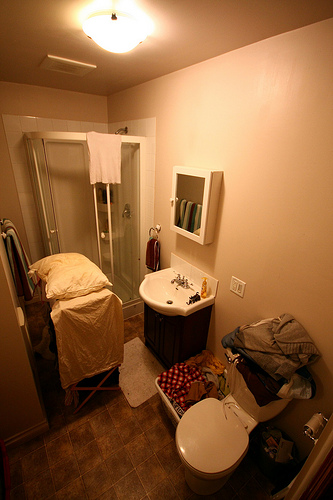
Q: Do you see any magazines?
A: No, there are no magazines.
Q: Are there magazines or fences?
A: No, there are no magazines or fences.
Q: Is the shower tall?
A: Yes, the shower is tall.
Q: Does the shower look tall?
A: Yes, the shower is tall.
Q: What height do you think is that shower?
A: The shower is tall.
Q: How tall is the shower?
A: The shower is tall.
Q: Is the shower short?
A: No, the shower is tall.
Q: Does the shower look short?
A: No, the shower is tall.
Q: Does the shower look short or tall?
A: The shower is tall.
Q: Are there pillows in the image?
A: Yes, there is a pillow.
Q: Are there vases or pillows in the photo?
A: Yes, there is a pillow.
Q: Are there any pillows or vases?
A: Yes, there is a pillow.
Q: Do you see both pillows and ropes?
A: No, there is a pillow but no ropes.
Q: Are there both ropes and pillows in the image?
A: No, there is a pillow but no ropes.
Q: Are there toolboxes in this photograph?
A: No, there are no toolboxes.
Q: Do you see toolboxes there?
A: No, there are no toolboxes.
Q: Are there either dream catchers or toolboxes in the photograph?
A: No, there are no toolboxes or dream catchers.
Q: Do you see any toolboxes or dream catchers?
A: No, there are no toolboxes or dream catchers.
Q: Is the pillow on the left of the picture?
A: Yes, the pillow is on the left of the image.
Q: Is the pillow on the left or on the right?
A: The pillow is on the left of the image.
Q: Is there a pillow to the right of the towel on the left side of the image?
A: Yes, there is a pillow to the right of the towel.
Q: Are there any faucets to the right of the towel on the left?
A: No, there is a pillow to the right of the towel.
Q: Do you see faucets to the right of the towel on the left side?
A: No, there is a pillow to the right of the towel.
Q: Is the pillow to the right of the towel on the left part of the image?
A: Yes, the pillow is to the right of the towel.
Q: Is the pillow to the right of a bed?
A: No, the pillow is to the right of the towel.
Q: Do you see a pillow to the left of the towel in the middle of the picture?
A: Yes, there is a pillow to the left of the towel.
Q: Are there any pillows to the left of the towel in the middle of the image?
A: Yes, there is a pillow to the left of the towel.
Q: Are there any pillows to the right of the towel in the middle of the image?
A: No, the pillow is to the left of the towel.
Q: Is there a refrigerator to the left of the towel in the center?
A: No, there is a pillow to the left of the towel.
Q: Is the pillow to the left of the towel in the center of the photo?
A: Yes, the pillow is to the left of the towel.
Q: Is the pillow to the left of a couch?
A: No, the pillow is to the left of the towel.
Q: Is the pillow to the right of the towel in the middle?
A: No, the pillow is to the left of the towel.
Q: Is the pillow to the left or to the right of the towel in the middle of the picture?
A: The pillow is to the left of the towel.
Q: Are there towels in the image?
A: Yes, there is a towel.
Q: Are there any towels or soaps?
A: Yes, there is a towel.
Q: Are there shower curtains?
A: No, there are no shower curtains.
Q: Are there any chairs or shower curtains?
A: No, there are no shower curtains or chairs.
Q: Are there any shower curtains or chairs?
A: No, there are no shower curtains or chairs.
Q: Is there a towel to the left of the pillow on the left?
A: Yes, there is a towel to the left of the pillow.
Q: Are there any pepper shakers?
A: No, there are no pepper shakers.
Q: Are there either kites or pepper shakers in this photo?
A: No, there are no pepper shakers or kites.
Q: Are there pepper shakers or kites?
A: No, there are no pepper shakers or kites.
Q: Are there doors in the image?
A: Yes, there is a door.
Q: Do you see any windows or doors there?
A: Yes, there is a door.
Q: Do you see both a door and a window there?
A: No, there is a door but no windows.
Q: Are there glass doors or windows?
A: Yes, there is a glass door.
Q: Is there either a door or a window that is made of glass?
A: Yes, the door is made of glass.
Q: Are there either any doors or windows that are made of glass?
A: Yes, the door is made of glass.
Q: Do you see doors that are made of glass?
A: Yes, there is a door that is made of glass.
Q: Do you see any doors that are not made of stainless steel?
A: Yes, there is a door that is made of glass.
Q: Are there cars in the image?
A: No, there are no cars.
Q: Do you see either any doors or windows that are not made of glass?
A: No, there is a door but it is made of glass.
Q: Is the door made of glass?
A: Yes, the door is made of glass.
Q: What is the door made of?
A: The door is made of glass.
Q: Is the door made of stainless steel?
A: No, the door is made of glass.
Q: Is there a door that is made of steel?
A: No, there is a door but it is made of glass.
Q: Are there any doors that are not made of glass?
A: No, there is a door but it is made of glass.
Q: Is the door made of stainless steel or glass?
A: The door is made of glass.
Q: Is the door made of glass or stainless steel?
A: The door is made of glass.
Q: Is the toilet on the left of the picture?
A: No, the toilet is on the right of the image.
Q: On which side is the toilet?
A: The toilet is on the right of the image.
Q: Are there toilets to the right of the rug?
A: Yes, there is a toilet to the right of the rug.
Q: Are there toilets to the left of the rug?
A: No, the toilet is to the right of the rug.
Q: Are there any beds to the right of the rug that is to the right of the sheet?
A: No, there is a toilet to the right of the rug.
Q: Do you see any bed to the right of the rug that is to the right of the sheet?
A: No, there is a toilet to the right of the rug.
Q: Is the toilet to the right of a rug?
A: Yes, the toilet is to the right of a rug.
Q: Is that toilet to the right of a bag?
A: No, the toilet is to the right of a rug.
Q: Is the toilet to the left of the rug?
A: No, the toilet is to the right of the rug.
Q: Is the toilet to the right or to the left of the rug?
A: The toilet is to the right of the rug.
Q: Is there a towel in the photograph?
A: Yes, there is a towel.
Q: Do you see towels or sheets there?
A: Yes, there is a towel.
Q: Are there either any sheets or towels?
A: Yes, there is a towel.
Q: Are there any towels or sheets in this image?
A: Yes, there is a towel.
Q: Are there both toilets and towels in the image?
A: Yes, there are both a towel and a toilet.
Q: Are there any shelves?
A: No, there are no shelves.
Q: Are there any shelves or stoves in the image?
A: No, there are no shelves or stoves.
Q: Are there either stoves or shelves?
A: No, there are no shelves or stoves.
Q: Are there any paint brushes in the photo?
A: No, there are no paint brushes.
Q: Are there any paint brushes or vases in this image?
A: No, there are no paint brushes or vases.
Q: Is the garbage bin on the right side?
A: Yes, the garbage bin is on the right of the image.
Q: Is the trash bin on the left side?
A: No, the trash bin is on the right of the image.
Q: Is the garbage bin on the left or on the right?
A: The garbage bin is on the right of the image.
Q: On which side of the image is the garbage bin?
A: The garbage bin is on the right of the image.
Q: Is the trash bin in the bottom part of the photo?
A: Yes, the trash bin is in the bottom of the image.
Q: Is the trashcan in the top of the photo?
A: No, the trashcan is in the bottom of the image.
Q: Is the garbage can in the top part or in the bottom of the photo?
A: The garbage can is in the bottom of the image.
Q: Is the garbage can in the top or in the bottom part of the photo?
A: The garbage can is in the bottom of the image.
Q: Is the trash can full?
A: Yes, the trash can is full.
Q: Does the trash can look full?
A: Yes, the trash can is full.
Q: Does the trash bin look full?
A: Yes, the trash bin is full.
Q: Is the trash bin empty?
A: No, the trash bin is full.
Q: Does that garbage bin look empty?
A: No, the garbage bin is full.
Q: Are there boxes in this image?
A: No, there are no boxes.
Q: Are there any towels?
A: Yes, there is a towel.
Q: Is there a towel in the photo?
A: Yes, there is a towel.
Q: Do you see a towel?
A: Yes, there is a towel.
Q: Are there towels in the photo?
A: Yes, there is a towel.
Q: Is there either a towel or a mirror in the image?
A: Yes, there is a towel.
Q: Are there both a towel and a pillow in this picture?
A: Yes, there are both a towel and a pillow.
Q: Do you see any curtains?
A: No, there are no curtains.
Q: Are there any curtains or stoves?
A: No, there are no curtains or stoves.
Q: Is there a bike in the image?
A: No, there are no bikes.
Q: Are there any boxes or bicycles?
A: No, there are no bicycles or boxes.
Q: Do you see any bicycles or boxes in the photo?
A: No, there are no bicycles or boxes.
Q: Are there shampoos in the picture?
A: No, there are no shampoos.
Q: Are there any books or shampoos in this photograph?
A: No, there are no shampoos or books.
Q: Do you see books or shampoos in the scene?
A: No, there are no shampoos or books.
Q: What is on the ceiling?
A: The light fixture is on the ceiling.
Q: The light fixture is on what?
A: The light fixture is on the ceiling.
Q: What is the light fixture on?
A: The light fixture is on the ceiling.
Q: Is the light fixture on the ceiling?
A: Yes, the light fixture is on the ceiling.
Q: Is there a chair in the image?
A: No, there are no chairs.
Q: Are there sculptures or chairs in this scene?
A: No, there are no chairs or sculptures.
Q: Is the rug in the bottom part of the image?
A: Yes, the rug is in the bottom of the image.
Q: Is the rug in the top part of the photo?
A: No, the rug is in the bottom of the image.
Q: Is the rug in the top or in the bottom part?
A: The rug is in the bottom of the image.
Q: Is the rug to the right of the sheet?
A: Yes, the rug is to the right of the sheet.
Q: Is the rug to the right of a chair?
A: No, the rug is to the right of the sheet.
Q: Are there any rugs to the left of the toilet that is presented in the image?
A: Yes, there is a rug to the left of the toilet.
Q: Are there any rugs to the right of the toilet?
A: No, the rug is to the left of the toilet.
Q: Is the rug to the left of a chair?
A: No, the rug is to the left of the toilet.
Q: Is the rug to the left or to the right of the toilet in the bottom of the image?
A: The rug is to the left of the toilet.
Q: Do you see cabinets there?
A: Yes, there is a cabinet.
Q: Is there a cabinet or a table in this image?
A: Yes, there is a cabinet.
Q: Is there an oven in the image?
A: No, there are no ovens.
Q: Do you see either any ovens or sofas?
A: No, there are no ovens or sofas.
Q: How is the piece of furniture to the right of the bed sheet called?
A: The piece of furniture is a cabinet.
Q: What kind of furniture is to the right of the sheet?
A: The piece of furniture is a cabinet.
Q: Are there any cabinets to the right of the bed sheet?
A: Yes, there is a cabinet to the right of the bed sheet.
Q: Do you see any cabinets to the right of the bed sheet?
A: Yes, there is a cabinet to the right of the bed sheet.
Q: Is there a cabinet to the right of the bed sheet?
A: Yes, there is a cabinet to the right of the bed sheet.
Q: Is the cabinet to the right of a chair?
A: No, the cabinet is to the right of the sheet.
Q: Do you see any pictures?
A: No, there are no pictures.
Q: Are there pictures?
A: No, there are no pictures.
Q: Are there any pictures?
A: No, there are no pictures.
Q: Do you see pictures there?
A: No, there are no pictures.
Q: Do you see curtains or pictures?
A: No, there are no pictures or curtains.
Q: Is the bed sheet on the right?
A: No, the bed sheet is on the left of the image.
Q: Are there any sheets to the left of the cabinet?
A: Yes, there is a sheet to the left of the cabinet.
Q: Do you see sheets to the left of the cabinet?
A: Yes, there is a sheet to the left of the cabinet.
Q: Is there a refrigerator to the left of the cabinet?
A: No, there is a sheet to the left of the cabinet.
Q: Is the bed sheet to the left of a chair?
A: No, the bed sheet is to the left of the cabinet.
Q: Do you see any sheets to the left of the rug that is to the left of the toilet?
A: Yes, there is a sheet to the left of the rug.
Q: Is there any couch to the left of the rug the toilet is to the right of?
A: No, there is a sheet to the left of the rug.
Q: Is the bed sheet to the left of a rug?
A: Yes, the bed sheet is to the left of a rug.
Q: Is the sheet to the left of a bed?
A: No, the sheet is to the left of a rug.